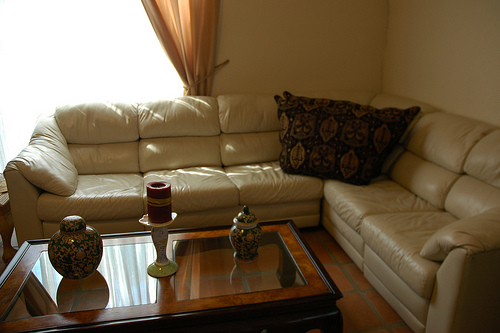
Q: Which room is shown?
A: It is a living room.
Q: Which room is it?
A: It is a living room.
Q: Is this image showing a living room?
A: Yes, it is showing a living room.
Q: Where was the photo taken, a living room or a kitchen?
A: It was taken at a living room.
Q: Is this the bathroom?
A: No, it is the living room.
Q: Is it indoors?
A: Yes, it is indoors.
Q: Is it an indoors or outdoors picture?
A: It is indoors.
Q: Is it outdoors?
A: No, it is indoors.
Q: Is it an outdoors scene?
A: No, it is indoors.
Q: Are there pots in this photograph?
A: Yes, there is a pot.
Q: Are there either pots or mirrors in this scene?
A: Yes, there is a pot.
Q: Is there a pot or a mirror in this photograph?
A: Yes, there is a pot.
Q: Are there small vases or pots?
A: Yes, there is a small pot.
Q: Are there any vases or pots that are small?
A: Yes, the pot is small.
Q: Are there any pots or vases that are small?
A: Yes, the pot is small.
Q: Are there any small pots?
A: Yes, there is a small pot.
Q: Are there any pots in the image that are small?
A: Yes, there is a pot that is small.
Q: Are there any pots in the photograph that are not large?
A: Yes, there is a small pot.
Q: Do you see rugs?
A: No, there are no rugs.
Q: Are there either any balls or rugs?
A: No, there are no rugs or balls.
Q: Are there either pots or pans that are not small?
A: No, there is a pot but it is small.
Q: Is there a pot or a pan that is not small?
A: No, there is a pot but it is small.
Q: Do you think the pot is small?
A: Yes, the pot is small.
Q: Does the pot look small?
A: Yes, the pot is small.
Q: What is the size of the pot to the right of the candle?
A: The pot is small.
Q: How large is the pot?
A: The pot is small.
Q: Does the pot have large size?
A: No, the pot is small.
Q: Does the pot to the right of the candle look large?
A: No, the pot is small.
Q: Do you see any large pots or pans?
A: No, there is a pot but it is small.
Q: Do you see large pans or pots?
A: No, there is a pot but it is small.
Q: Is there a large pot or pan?
A: No, there is a pot but it is small.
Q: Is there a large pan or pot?
A: No, there is a pot but it is small.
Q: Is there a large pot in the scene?
A: No, there is a pot but it is small.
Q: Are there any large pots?
A: No, there is a pot but it is small.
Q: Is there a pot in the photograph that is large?
A: No, there is a pot but it is small.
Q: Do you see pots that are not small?
A: No, there is a pot but it is small.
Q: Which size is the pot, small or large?
A: The pot is small.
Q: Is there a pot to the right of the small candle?
A: Yes, there is a pot to the right of the candle.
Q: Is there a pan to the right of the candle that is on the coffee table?
A: No, there is a pot to the right of the candle.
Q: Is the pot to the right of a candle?
A: Yes, the pot is to the right of a candle.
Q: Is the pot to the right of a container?
A: No, the pot is to the right of a candle.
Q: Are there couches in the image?
A: Yes, there is a couch.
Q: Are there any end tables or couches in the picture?
A: Yes, there is a couch.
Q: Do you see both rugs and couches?
A: No, there is a couch but no rugs.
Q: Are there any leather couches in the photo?
A: Yes, there is a couch that is made of leather.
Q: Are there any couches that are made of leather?
A: Yes, there is a couch that is made of leather.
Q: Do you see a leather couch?
A: Yes, there is a couch that is made of leather.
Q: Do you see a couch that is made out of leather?
A: Yes, there is a couch that is made of leather.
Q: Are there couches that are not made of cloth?
A: Yes, there is a couch that is made of leather.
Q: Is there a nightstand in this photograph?
A: No, there are no nightstands.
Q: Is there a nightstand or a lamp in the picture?
A: No, there are no nightstands or lamps.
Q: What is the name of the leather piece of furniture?
A: The piece of furniture is a couch.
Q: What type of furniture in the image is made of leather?
A: The furniture is a couch.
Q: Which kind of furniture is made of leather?
A: The furniture is a couch.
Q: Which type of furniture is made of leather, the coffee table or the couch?
A: The couch is made of leather.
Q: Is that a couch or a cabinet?
A: That is a couch.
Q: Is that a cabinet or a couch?
A: That is a couch.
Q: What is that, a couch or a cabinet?
A: That is a couch.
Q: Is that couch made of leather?
A: Yes, the couch is made of leather.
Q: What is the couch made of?
A: The couch is made of leather.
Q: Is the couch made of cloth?
A: No, the couch is made of leather.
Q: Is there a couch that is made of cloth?
A: No, there is a couch but it is made of leather.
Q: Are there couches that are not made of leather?
A: No, there is a couch but it is made of leather.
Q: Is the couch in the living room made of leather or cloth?
A: The couch is made of leather.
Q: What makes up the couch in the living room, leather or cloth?
A: The couch is made of leather.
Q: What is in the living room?
A: The couch is in the living room.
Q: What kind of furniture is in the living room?
A: The piece of furniture is a couch.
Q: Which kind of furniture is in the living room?
A: The piece of furniture is a couch.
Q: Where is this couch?
A: The couch is in the living room.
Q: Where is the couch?
A: The couch is in the living room.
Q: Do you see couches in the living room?
A: Yes, there is a couch in the living room.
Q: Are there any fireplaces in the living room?
A: No, there is a couch in the living room.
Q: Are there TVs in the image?
A: No, there are no tvs.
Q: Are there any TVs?
A: No, there are no tvs.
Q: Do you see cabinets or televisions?
A: No, there are no televisions or cabinets.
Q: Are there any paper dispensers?
A: No, there are no paper dispensers.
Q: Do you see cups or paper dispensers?
A: No, there are no paper dispensers or cups.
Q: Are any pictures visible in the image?
A: No, there are no pictures.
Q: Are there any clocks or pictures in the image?
A: No, there are no pictures or clocks.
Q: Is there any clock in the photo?
A: No, there are no clocks.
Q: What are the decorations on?
A: The decorations are on the coffee table.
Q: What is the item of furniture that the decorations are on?
A: The piece of furniture is a coffee table.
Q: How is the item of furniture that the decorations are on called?
A: The piece of furniture is a coffee table.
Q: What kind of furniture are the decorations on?
A: The decorations are on the coffee table.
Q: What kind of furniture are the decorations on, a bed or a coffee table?
A: The decorations are on a coffee table.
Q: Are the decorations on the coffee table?
A: Yes, the decorations are on the coffee table.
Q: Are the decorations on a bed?
A: No, the decorations are on the coffee table.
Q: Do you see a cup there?
A: No, there are no cups.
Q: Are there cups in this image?
A: No, there are no cups.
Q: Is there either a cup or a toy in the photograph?
A: No, there are no cups or toys.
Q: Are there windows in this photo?
A: Yes, there is a window.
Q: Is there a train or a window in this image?
A: Yes, there is a window.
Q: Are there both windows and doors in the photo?
A: No, there is a window but no doors.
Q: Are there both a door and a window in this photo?
A: No, there is a window but no doors.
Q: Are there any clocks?
A: No, there are no clocks.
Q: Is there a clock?
A: No, there are no clocks.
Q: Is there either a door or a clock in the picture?
A: No, there are no clocks or doors.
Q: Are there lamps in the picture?
A: No, there are no lamps.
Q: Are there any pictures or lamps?
A: No, there are no lamps or pictures.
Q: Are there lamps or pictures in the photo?
A: No, there are no lamps or pictures.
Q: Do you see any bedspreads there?
A: No, there are no bedspreads.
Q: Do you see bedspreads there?
A: No, there are no bedspreads.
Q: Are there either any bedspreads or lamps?
A: No, there are no bedspreads or lamps.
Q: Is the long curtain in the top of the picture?
A: Yes, the curtain is in the top of the image.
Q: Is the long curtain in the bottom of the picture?
A: No, the curtain is in the top of the image.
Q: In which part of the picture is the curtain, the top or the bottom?
A: The curtain is in the top of the image.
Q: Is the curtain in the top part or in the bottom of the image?
A: The curtain is in the top of the image.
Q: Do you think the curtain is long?
A: Yes, the curtain is long.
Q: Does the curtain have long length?
A: Yes, the curtain is long.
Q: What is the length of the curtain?
A: The curtain is long.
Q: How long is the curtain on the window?
A: The curtain is long.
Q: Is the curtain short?
A: No, the curtain is long.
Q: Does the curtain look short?
A: No, the curtain is long.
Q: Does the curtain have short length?
A: No, the curtain is long.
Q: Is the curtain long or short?
A: The curtain is long.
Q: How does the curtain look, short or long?
A: The curtain is long.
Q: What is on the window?
A: The curtain is on the window.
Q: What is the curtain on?
A: The curtain is on the window.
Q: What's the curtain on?
A: The curtain is on the window.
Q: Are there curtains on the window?
A: Yes, there is a curtain on the window.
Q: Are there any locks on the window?
A: No, there is a curtain on the window.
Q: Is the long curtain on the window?
A: Yes, the curtain is on the window.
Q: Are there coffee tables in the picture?
A: Yes, there is a coffee table.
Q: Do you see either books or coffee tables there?
A: Yes, there is a coffee table.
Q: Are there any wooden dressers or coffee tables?
A: Yes, there is a wood coffee table.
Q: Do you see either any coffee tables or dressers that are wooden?
A: Yes, the coffee table is wooden.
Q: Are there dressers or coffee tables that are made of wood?
A: Yes, the coffee table is made of wood.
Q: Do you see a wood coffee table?
A: Yes, there is a wood coffee table.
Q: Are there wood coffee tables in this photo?
A: Yes, there is a wood coffee table.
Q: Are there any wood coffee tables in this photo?
A: Yes, there is a wood coffee table.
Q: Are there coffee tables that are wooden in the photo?
A: Yes, there is a wood coffee table.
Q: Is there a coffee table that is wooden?
A: Yes, there is a coffee table that is wooden.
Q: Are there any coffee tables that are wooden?
A: Yes, there is a coffee table that is wooden.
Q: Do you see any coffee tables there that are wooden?
A: Yes, there is a coffee table that is wooden.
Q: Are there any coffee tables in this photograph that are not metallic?
A: Yes, there is a wooden coffee table.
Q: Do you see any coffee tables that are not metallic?
A: Yes, there is a wooden coffee table.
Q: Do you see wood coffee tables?
A: Yes, there is a coffee table that is made of wood.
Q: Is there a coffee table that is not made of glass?
A: Yes, there is a coffee table that is made of wood.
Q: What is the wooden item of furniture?
A: The piece of furniture is a coffee table.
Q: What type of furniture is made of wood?
A: The furniture is a coffee table.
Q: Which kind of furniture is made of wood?
A: The furniture is a coffee table.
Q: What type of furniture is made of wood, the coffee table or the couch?
A: The coffee table is made of wood.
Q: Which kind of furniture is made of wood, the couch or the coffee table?
A: The coffee table is made of wood.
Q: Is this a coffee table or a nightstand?
A: This is a coffee table.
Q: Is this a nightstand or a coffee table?
A: This is a coffee table.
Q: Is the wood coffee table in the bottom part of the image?
A: Yes, the coffee table is in the bottom of the image.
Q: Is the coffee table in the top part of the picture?
A: No, the coffee table is in the bottom of the image.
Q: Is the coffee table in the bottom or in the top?
A: The coffee table is in the bottom of the image.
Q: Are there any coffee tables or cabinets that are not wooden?
A: No, there is a coffee table but it is wooden.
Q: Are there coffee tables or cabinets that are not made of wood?
A: No, there is a coffee table but it is made of wood.